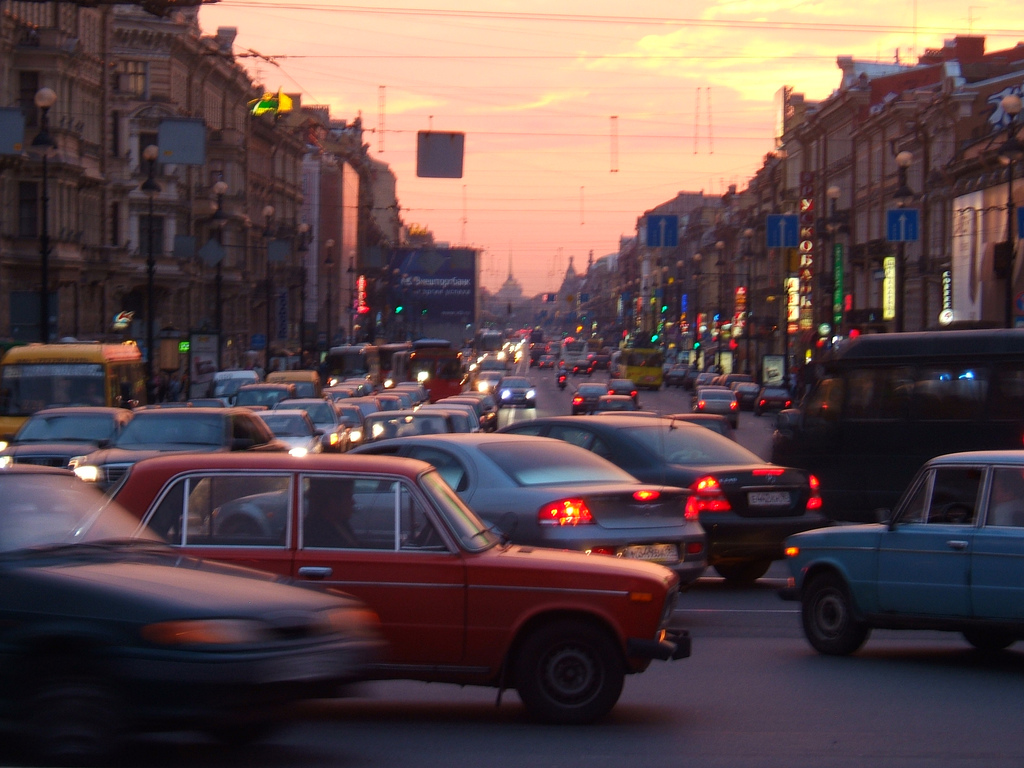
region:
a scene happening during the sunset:
[14, 16, 1021, 753]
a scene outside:
[2, 12, 1021, 747]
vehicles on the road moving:
[9, 263, 1021, 764]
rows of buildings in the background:
[5, 3, 1018, 400]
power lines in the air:
[125, 10, 1020, 239]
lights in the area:
[534, 177, 958, 387]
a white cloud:
[461, 74, 621, 129]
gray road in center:
[262, 314, 1019, 764]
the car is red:
[114, 441, 704, 729]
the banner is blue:
[875, 199, 927, 260]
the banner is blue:
[759, 207, 802, 247]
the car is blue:
[755, 421, 1012, 701]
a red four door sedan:
[95, 418, 706, 735]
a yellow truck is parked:
[13, 324, 146, 445]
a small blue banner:
[629, 191, 684, 264]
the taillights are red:
[681, 456, 831, 533]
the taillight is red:
[521, 484, 591, 546]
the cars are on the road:
[41, 394, 1012, 767]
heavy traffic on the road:
[6, 329, 1016, 762]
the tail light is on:
[549, 473, 822, 550]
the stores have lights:
[536, 199, 888, 373]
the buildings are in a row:
[25, 22, 408, 393]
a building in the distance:
[480, 247, 537, 308]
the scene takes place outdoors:
[15, 0, 1018, 763]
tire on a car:
[514, 618, 642, 721]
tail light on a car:
[522, 490, 622, 536]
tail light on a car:
[667, 476, 713, 531]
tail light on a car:
[775, 443, 851, 507]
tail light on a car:
[678, 462, 736, 504]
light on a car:
[133, 607, 255, 665]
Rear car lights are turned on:
[516, 472, 710, 543]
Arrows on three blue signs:
[631, 187, 929, 264]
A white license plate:
[727, 468, 804, 523]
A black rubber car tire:
[781, 545, 880, 663]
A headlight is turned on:
[51, 438, 116, 497]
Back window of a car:
[605, 402, 789, 475]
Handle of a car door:
[931, 517, 983, 568]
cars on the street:
[75, 173, 910, 680]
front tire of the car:
[455, 598, 656, 748]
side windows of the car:
[158, 448, 428, 584]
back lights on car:
[648, 440, 854, 565]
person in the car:
[266, 449, 419, 564]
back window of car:
[613, 404, 778, 491]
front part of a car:
[87, 531, 414, 735]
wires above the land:
[362, 8, 694, 209]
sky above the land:
[352, 14, 697, 204]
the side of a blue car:
[763, 446, 1021, 661]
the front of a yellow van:
[0, 334, 138, 453]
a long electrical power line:
[241, 38, 839, 71]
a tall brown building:
[778, 62, 972, 350]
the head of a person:
[301, 477, 365, 522]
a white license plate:
[746, 484, 791, 504]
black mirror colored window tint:
[476, 436, 626, 487]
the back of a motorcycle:
[557, 372, 568, 388]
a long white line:
[664, 593, 807, 620]